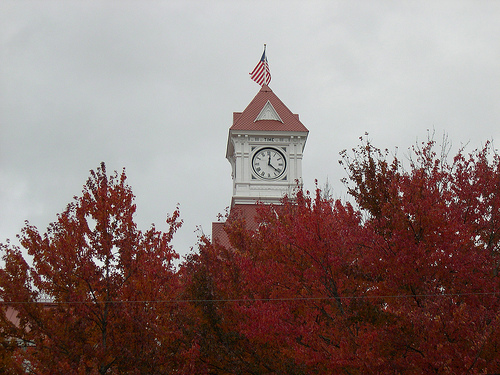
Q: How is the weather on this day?
A: It is cloudy.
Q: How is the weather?
A: It is cloudy.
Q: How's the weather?
A: It is cloudy.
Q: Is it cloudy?
A: Yes, it is cloudy.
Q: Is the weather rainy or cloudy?
A: It is cloudy.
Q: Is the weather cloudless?
A: No, it is cloudy.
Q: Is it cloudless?
A: No, it is cloudy.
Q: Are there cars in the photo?
A: No, there are no cars.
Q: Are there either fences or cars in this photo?
A: No, there are no cars or fences.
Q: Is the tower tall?
A: Yes, the tower is tall.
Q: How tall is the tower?
A: The tower is tall.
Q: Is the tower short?
A: No, the tower is tall.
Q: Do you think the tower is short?
A: No, the tower is tall.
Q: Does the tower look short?
A: No, the tower is tall.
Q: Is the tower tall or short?
A: The tower is tall.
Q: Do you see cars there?
A: No, there are no cars.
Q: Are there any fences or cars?
A: No, there are no cars or fences.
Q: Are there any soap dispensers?
A: No, there are no soap dispensers.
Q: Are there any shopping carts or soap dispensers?
A: No, there are no soap dispensers or shopping carts.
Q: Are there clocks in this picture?
A: Yes, there is a clock.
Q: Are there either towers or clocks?
A: Yes, there is a clock.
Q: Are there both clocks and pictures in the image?
A: No, there is a clock but no pictures.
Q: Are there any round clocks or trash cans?
A: Yes, there is a round clock.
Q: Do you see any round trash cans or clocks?
A: Yes, there is a round clock.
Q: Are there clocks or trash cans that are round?
A: Yes, the clock is round.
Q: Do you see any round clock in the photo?
A: Yes, there is a round clock.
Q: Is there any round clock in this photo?
A: Yes, there is a round clock.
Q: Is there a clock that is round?
A: Yes, there is a clock that is round.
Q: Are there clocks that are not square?
A: Yes, there is a round clock.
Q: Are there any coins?
A: No, there are no coins.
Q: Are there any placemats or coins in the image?
A: No, there are no coins or placemats.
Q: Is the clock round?
A: Yes, the clock is round.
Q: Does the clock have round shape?
A: Yes, the clock is round.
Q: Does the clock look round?
A: Yes, the clock is round.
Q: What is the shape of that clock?
A: The clock is round.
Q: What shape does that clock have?
A: The clock has round shape.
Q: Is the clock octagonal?
A: No, the clock is round.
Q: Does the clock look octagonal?
A: No, the clock is round.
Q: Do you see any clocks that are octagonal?
A: No, there is a clock but it is round.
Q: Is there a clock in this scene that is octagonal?
A: No, there is a clock but it is round.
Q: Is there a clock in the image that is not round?
A: No, there is a clock but it is round.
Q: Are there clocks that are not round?
A: No, there is a clock but it is round.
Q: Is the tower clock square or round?
A: The clock is round.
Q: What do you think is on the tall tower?
A: The clock is on the tower.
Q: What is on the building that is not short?
A: The clock is on the tower.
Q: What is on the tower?
A: The clock is on the tower.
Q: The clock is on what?
A: The clock is on the tower.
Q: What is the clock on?
A: The clock is on the tower.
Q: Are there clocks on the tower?
A: Yes, there is a clock on the tower.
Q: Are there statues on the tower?
A: No, there is a clock on the tower.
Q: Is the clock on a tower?
A: Yes, the clock is on a tower.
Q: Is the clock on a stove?
A: No, the clock is on a tower.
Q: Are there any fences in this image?
A: No, there are no fences.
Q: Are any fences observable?
A: No, there are no fences.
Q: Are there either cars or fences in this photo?
A: No, there are no fences or cars.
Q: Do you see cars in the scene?
A: No, there are no cars.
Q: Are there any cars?
A: No, there are no cars.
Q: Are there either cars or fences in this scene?
A: No, there are no cars or fences.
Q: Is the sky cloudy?
A: Yes, the sky is cloudy.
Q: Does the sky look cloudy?
A: Yes, the sky is cloudy.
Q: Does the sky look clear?
A: No, the sky is cloudy.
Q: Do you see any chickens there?
A: No, there are no chickens.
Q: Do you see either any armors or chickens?
A: No, there are no chickens or armors.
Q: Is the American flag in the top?
A: Yes, the American flag is in the top of the image.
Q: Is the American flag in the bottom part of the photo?
A: No, the American flag is in the top of the image.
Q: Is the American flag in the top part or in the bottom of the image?
A: The American flag is in the top of the image.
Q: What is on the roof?
A: The American flag is on the roof.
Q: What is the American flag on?
A: The American flag is on the roof.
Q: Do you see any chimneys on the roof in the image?
A: No, there is an American flag on the roof.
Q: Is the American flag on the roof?
A: Yes, the American flag is on the roof.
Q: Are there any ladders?
A: No, there are no ladders.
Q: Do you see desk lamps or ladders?
A: No, there are no ladders or desk lamps.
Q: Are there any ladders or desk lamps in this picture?
A: No, there are no ladders or desk lamps.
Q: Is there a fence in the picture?
A: No, there are no fences.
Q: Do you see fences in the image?
A: No, there are no fences.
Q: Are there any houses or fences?
A: No, there are no fences or houses.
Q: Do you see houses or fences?
A: No, there are no fences or houses.